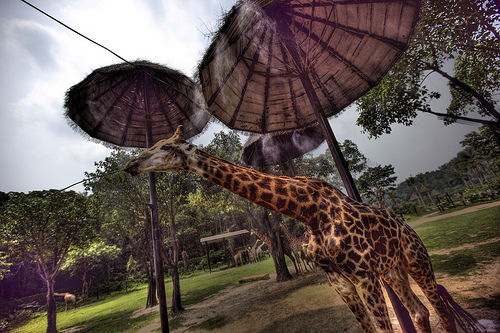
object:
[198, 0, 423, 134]
umbrella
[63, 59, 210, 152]
umbrella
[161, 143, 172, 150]
eye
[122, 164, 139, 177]
mouth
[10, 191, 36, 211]
leaves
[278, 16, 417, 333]
pole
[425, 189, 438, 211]
huts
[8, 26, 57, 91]
cloud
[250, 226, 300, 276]
giraffe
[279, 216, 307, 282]
bark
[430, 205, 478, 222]
dirt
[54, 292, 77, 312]
giraffe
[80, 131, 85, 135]
frills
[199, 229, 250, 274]
structure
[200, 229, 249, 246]
roof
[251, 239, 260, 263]
giraffes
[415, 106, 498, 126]
limb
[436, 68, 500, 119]
limb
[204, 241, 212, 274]
pole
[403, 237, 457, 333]
legs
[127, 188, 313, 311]
building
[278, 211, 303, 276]
animals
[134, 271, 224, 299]
grass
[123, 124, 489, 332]
giraffe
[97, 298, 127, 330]
grass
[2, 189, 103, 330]
tree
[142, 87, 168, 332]
pole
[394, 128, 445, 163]
sky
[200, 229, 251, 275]
canopy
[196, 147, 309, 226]
neck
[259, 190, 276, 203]
spots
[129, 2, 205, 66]
clouds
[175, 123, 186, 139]
horns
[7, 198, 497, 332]
ground